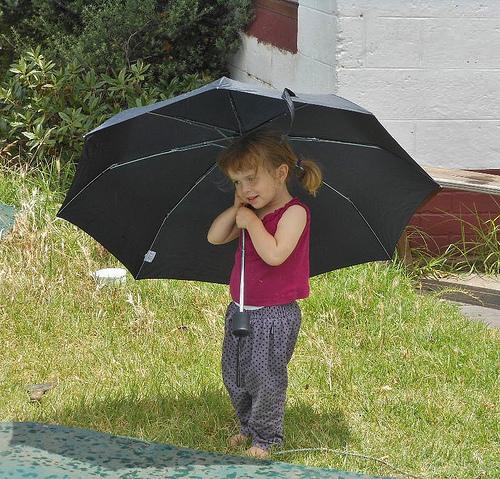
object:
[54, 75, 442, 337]
umbrella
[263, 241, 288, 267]
elbow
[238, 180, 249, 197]
nose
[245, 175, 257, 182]
eye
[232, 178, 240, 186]
eye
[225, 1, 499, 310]
building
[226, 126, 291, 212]
head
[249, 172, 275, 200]
cheek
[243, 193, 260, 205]
mouth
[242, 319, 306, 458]
legs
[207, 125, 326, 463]
girl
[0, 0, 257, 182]
bushes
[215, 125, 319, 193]
hair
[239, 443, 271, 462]
feet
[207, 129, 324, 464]
child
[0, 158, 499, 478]
grass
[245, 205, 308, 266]
arm